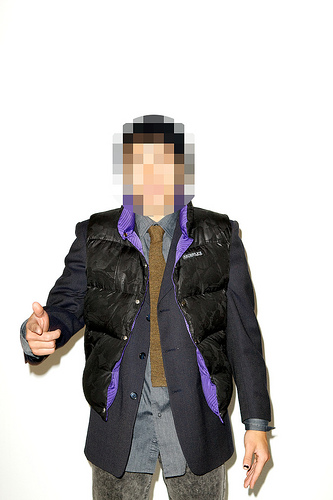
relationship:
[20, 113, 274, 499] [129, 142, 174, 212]
man has face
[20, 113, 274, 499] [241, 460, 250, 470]
man wearing nailpolish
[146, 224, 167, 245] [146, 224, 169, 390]
knot on top of tie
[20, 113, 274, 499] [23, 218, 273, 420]
man wearing shirt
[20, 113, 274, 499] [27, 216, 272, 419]
man wearing jacket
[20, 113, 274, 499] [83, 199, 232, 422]
man wearing vest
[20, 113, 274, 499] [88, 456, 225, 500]
man wearing jean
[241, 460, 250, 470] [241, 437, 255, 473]
nailpolish on top of thumb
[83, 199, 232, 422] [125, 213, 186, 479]
vest has shirt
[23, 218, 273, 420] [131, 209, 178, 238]
shirt has collar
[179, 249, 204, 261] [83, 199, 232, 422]
letters on front of vest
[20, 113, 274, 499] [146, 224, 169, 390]
man wearing tie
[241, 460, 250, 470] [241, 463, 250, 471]
nailpolish on top of nail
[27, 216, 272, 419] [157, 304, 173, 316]
jacket has button hole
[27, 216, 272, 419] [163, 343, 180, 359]
jacket has button hole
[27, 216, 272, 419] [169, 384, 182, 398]
jacket has button hole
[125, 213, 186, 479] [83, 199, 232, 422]
shirt inside vest